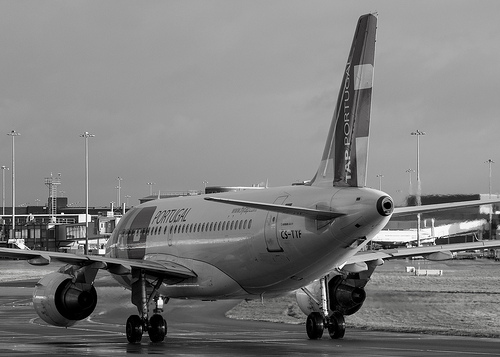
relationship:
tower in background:
[43, 170, 62, 214] [0, 1, 499, 258]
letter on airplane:
[183, 207, 191, 222] [0, 13, 500, 344]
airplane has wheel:
[0, 13, 500, 344] [126, 316, 142, 344]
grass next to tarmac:
[226, 254, 500, 338] [1, 270, 498, 356]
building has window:
[0, 197, 130, 248] [29, 227, 41, 239]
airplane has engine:
[0, 13, 500, 344] [32, 270, 98, 327]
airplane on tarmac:
[0, 13, 500, 344] [1, 270, 498, 356]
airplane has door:
[0, 13, 500, 344] [265, 195, 288, 252]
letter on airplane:
[152, 210, 161, 225] [0, 13, 500, 344]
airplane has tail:
[0, 13, 500, 344] [304, 13, 379, 188]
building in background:
[0, 197, 130, 248] [0, 1, 499, 258]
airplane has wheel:
[0, 13, 500, 344] [329, 313, 345, 340]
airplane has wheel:
[0, 13, 500, 344] [148, 314, 167, 342]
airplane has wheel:
[0, 13, 500, 344] [307, 312, 325, 337]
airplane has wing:
[0, 13, 500, 344] [1, 245, 198, 282]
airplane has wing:
[0, 13, 500, 344] [345, 240, 499, 263]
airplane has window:
[0, 13, 500, 344] [162, 224, 168, 234]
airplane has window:
[0, 13, 500, 344] [247, 219, 251, 229]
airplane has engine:
[0, 13, 500, 344] [295, 273, 366, 317]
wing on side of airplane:
[1, 245, 198, 282] [0, 13, 500, 344]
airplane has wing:
[0, 13, 500, 344] [204, 196, 347, 223]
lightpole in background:
[7, 129, 22, 231] [0, 1, 499, 258]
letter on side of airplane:
[183, 207, 191, 222] [0, 13, 500, 344]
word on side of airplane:
[150, 207, 191, 223] [0, 13, 500, 344]